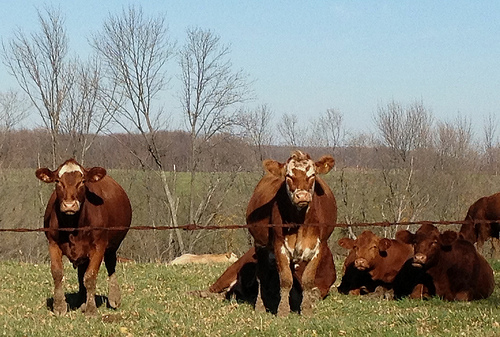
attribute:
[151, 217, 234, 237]
wire — barbed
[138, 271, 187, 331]
field — grass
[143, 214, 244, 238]
wire — barbed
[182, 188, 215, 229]
twig — large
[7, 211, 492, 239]
wire — barbed, green, thin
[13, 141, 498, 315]
cow — sitting, white, brown, looking, facing, resting, standing, laying, ADULT, baby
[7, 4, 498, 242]
trees — bare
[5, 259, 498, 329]
grass — green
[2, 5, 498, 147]
sky — blue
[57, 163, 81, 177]
spot — white